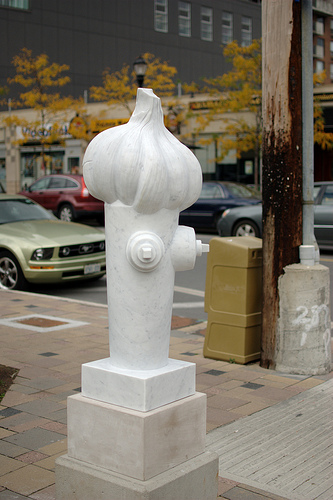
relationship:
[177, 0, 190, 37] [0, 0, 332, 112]
window on building